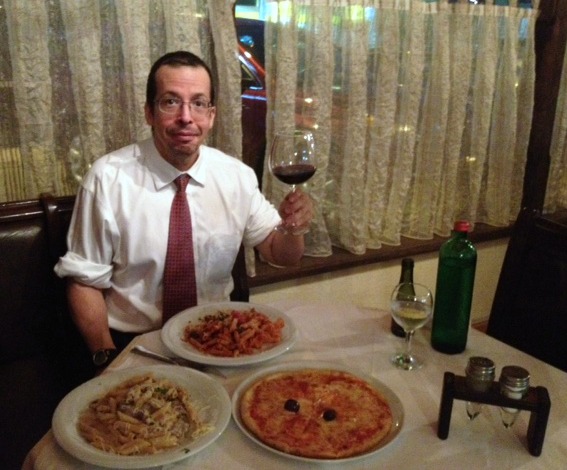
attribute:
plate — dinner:
[157, 293, 300, 369]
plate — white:
[64, 333, 218, 436]